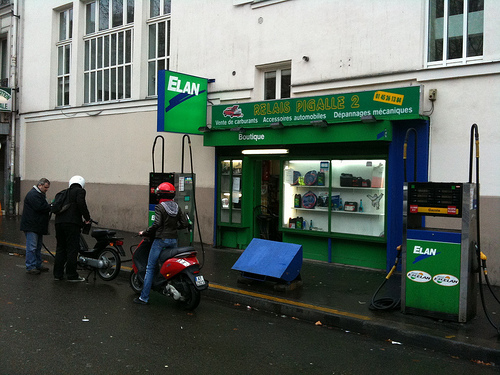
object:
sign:
[156, 69, 209, 136]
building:
[0, 0, 500, 287]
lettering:
[167, 75, 179, 93]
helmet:
[156, 181, 177, 199]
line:
[207, 283, 374, 321]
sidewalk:
[0, 214, 500, 350]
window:
[46, 0, 172, 110]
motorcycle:
[128, 229, 210, 312]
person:
[132, 180, 193, 305]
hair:
[36, 177, 51, 186]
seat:
[158, 245, 196, 263]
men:
[49, 174, 94, 283]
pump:
[368, 243, 403, 314]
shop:
[201, 113, 429, 275]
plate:
[194, 275, 207, 287]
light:
[241, 149, 289, 155]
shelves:
[331, 210, 384, 217]